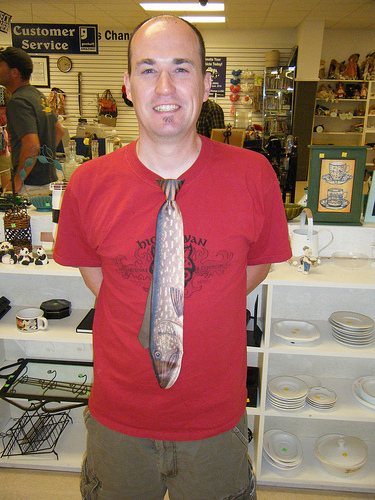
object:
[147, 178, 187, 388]
fish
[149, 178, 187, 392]
tie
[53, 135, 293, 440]
shirt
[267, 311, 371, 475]
ceramics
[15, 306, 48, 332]
cup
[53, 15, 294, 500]
man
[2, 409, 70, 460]
steamer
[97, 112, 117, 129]
purses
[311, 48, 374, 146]
dolls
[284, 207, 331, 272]
watering can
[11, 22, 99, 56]
sign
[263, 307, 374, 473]
dishes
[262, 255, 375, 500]
shelves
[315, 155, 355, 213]
plaque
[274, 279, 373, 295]
shelf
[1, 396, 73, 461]
rack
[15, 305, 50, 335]
shelf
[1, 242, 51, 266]
ceramics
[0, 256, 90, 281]
shelf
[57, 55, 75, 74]
clock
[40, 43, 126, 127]
wall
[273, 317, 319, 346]
plate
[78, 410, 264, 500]
pants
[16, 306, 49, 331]
mug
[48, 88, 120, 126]
bags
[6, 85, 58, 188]
shirt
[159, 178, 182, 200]
clip